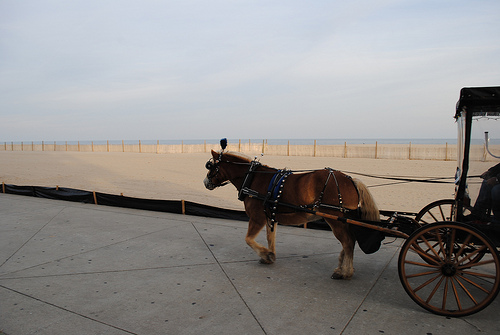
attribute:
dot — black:
[254, 289, 264, 296]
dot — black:
[208, 239, 220, 251]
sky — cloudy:
[2, 2, 499, 146]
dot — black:
[230, 305, 250, 324]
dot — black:
[86, 255, 99, 265]